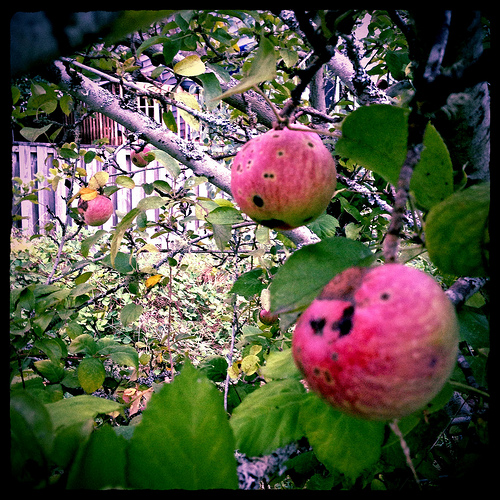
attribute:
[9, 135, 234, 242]
wooden fence — brown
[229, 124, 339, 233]
fruit — pink, green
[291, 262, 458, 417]
fruit — green, pink, red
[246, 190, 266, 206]
hole — rotten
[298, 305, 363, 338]
hole — rotten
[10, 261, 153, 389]
leaves — green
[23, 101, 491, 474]
leaves — green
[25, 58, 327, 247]
branch — large, brown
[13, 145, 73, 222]
fence — wooden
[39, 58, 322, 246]
tree branch — grey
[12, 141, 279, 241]
fence — wooden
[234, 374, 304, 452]
leaf — small, green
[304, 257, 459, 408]
fruit — pink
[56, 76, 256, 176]
branch — brown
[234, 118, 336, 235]
fruit — green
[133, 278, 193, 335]
vegetation — green, red, orange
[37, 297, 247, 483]
leaves — green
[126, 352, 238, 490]
leaf — green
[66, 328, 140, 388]
leaf — large, green